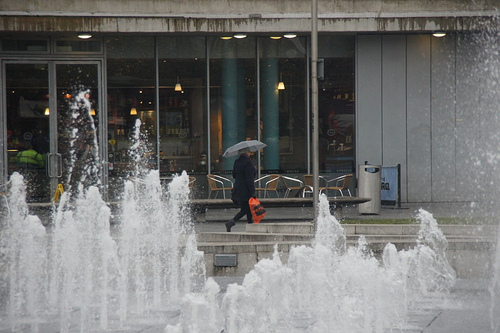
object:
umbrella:
[221, 140, 267, 159]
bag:
[249, 197, 267, 224]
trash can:
[358, 162, 381, 215]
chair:
[327, 174, 353, 197]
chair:
[303, 175, 328, 198]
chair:
[281, 175, 304, 198]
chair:
[254, 174, 280, 199]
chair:
[207, 174, 234, 199]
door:
[0, 57, 106, 204]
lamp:
[277, 73, 285, 90]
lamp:
[174, 76, 182, 91]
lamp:
[129, 103, 138, 118]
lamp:
[91, 104, 96, 115]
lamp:
[45, 107, 50, 115]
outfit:
[231, 155, 257, 223]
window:
[104, 33, 160, 202]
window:
[156, 31, 210, 201]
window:
[207, 31, 258, 200]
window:
[258, 33, 310, 198]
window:
[308, 31, 356, 197]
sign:
[365, 160, 410, 209]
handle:
[55, 153, 62, 178]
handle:
[47, 153, 54, 178]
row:
[189, 174, 352, 200]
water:
[0, 0, 499, 333]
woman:
[225, 147, 257, 232]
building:
[0, 1, 499, 251]